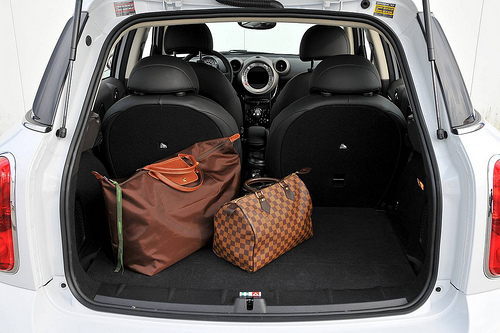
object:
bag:
[209, 166, 320, 276]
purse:
[90, 130, 247, 276]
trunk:
[50, 4, 457, 320]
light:
[485, 153, 499, 278]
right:
[452, 1, 496, 328]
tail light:
[0, 152, 20, 278]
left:
[2, 3, 44, 333]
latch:
[56, 2, 89, 141]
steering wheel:
[184, 45, 236, 85]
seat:
[260, 49, 415, 211]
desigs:
[247, 193, 274, 216]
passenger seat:
[270, 25, 381, 129]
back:
[96, 59, 416, 298]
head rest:
[161, 23, 213, 61]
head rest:
[296, 21, 355, 61]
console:
[233, 50, 287, 128]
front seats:
[138, 23, 244, 123]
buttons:
[253, 108, 257, 111]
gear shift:
[243, 125, 269, 148]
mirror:
[236, 19, 277, 35]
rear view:
[251, 21, 272, 29]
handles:
[143, 151, 199, 175]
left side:
[115, 32, 195, 134]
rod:
[420, 1, 449, 143]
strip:
[113, 176, 127, 276]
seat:
[105, 50, 244, 170]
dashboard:
[222, 53, 290, 97]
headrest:
[119, 53, 202, 98]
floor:
[318, 197, 407, 279]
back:
[103, 52, 243, 177]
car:
[0, 0, 495, 330]